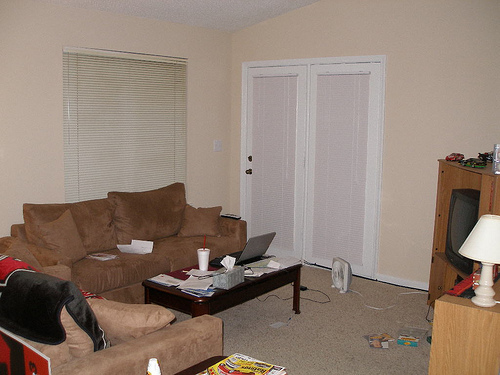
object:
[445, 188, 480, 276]
television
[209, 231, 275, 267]
computer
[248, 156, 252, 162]
lock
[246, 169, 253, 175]
doorknob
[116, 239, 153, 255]
paperwork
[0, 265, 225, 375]
couch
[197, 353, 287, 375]
magazines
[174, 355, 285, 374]
end table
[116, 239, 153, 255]
paper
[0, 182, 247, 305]
couch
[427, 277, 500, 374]
table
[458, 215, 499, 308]
lamp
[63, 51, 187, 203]
blinds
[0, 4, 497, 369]
room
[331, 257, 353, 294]
box fan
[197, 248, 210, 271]
cup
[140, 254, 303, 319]
table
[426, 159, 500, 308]
stand sitting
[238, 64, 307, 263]
door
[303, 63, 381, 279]
door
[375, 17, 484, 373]
corner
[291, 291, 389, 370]
floor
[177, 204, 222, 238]
pillow